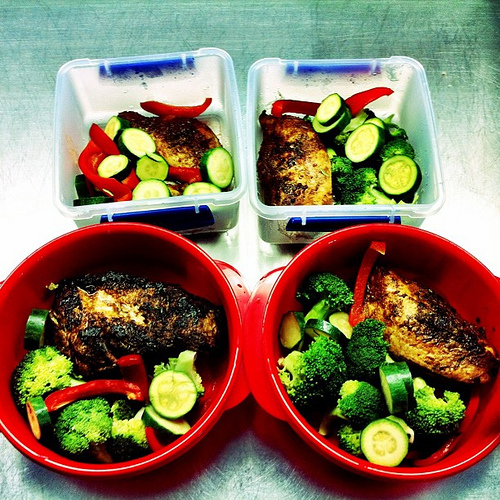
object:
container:
[46, 47, 248, 240]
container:
[242, 56, 446, 248]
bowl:
[2, 216, 259, 484]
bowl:
[240, 215, 500, 499]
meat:
[353, 257, 498, 391]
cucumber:
[374, 355, 420, 412]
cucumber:
[358, 410, 411, 472]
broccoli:
[342, 318, 390, 374]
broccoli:
[278, 331, 349, 415]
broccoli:
[329, 375, 386, 431]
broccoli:
[283, 269, 356, 333]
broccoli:
[406, 371, 468, 445]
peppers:
[43, 347, 156, 412]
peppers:
[140, 422, 169, 455]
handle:
[283, 57, 385, 78]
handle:
[96, 51, 193, 78]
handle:
[287, 211, 403, 239]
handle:
[93, 200, 220, 243]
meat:
[41, 261, 230, 385]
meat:
[255, 99, 337, 209]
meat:
[111, 107, 231, 181]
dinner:
[277, 231, 499, 470]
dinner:
[11, 264, 224, 465]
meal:
[69, 87, 240, 212]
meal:
[253, 76, 427, 212]